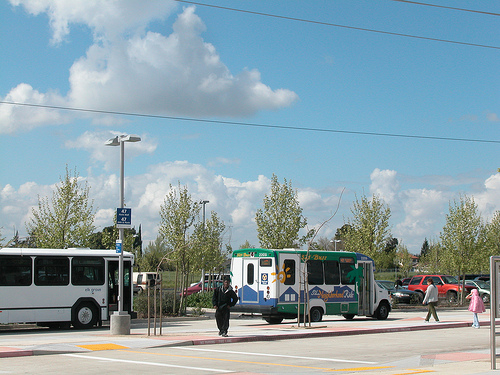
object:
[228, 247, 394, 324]
tempo van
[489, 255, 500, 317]
sign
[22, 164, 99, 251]
trees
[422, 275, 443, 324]
woman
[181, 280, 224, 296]
car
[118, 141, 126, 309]
post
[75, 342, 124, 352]
paint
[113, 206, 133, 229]
sign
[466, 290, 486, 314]
dress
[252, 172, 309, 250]
tree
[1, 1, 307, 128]
cloud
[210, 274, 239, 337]
man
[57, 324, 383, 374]
cross walk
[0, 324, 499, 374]
street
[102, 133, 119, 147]
lamp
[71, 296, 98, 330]
tire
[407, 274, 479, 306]
suv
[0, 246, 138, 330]
city bus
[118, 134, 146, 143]
lamp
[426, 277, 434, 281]
black hat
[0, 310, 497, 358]
sidewalk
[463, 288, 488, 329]
girl